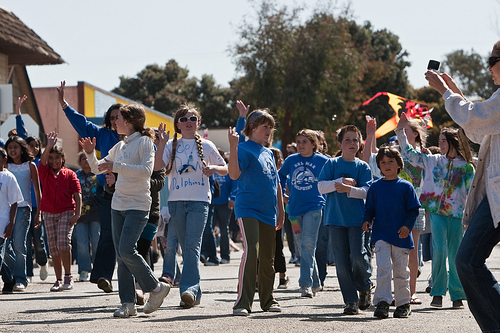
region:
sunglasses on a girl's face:
[177, 112, 201, 126]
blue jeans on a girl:
[108, 204, 163, 302]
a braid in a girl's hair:
[193, 134, 210, 166]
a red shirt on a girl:
[34, 160, 82, 213]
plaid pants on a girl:
[40, 208, 73, 256]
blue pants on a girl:
[426, 207, 464, 300]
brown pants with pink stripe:
[234, 214, 277, 312]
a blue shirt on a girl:
[234, 139, 280, 226]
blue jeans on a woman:
[456, 194, 498, 332]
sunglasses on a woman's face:
[485, 54, 499, 64]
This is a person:
[225, 99, 287, 324]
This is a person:
[278, 116, 331, 312]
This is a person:
[363, 136, 440, 331]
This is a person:
[322, 113, 372, 313]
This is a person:
[157, 101, 223, 313]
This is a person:
[110, 105, 173, 330]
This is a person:
[35, 128, 92, 302]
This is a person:
[2, 128, 47, 287]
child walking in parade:
[361, 143, 422, 318]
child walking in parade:
[315, 125, 373, 323]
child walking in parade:
[276, 129, 328, 303]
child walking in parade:
[221, 108, 291, 318]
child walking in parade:
[153, 102, 228, 311]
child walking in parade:
[79, 103, 178, 324]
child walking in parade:
[33, 127, 84, 293]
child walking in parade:
[4, 138, 46, 283]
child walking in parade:
[0, 150, 19, 297]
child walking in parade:
[55, 80, 120, 293]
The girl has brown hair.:
[166, 99, 208, 181]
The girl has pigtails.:
[167, 104, 207, 184]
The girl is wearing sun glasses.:
[168, 107, 205, 128]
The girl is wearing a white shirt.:
[157, 131, 223, 210]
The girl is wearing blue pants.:
[164, 188, 208, 305]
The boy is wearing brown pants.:
[231, 203, 279, 325]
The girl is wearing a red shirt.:
[21, 155, 85, 222]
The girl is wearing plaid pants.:
[38, 204, 77, 254]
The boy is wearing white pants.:
[361, 222, 425, 317]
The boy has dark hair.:
[370, 143, 412, 181]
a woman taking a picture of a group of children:
[422, 40, 498, 331]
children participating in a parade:
[0, 79, 475, 319]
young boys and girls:
[0, 80, 472, 320]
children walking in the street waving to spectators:
[0, 78, 473, 320]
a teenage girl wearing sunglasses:
[165, 105, 227, 307]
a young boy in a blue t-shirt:
[360, 143, 421, 316]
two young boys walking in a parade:
[315, 125, 422, 319]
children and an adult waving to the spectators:
[0, 79, 464, 321]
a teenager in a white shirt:
[75, 103, 171, 318]